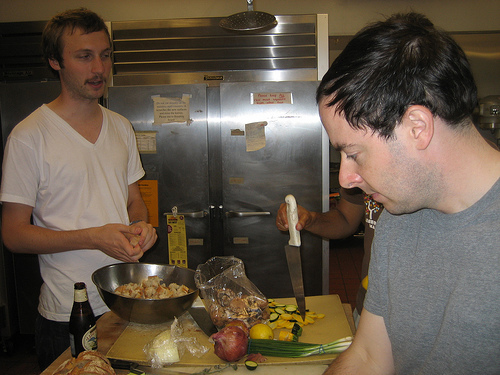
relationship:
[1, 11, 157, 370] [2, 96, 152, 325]
guys wears shirt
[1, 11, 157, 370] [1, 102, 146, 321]
guys wears tshirt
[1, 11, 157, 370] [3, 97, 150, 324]
guys wears white shirt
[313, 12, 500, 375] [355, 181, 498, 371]
guys wears shirt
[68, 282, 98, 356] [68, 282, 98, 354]
beer in bottle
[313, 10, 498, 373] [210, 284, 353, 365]
guys prepares food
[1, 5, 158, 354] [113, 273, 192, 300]
guys prepares food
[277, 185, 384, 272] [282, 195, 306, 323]
guy holds knife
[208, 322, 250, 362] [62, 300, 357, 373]
red onion on table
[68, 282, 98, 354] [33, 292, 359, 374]
bottle on counter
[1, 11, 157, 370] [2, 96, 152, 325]
guys in shirt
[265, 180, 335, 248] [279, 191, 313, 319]
hand holding knife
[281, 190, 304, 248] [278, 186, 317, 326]
handle on knife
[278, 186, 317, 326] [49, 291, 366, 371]
knife stuck into table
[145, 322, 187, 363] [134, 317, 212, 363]
onion wrapped in plastic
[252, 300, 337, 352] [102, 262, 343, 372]
sliced vegetables on table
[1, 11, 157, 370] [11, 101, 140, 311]
guys wearing shirt.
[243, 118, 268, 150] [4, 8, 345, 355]
note taped to refrigerater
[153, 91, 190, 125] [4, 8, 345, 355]
note taped to refrigerater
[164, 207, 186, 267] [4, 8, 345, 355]
note taped to refrigerater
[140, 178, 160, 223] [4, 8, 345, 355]
note taped to refrigerater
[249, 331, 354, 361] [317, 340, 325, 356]
onions tied with rubber band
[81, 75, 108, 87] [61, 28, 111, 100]
mustache on man's face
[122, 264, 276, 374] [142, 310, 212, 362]
item wrapped in cellophane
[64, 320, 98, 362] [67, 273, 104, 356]
label on bottle